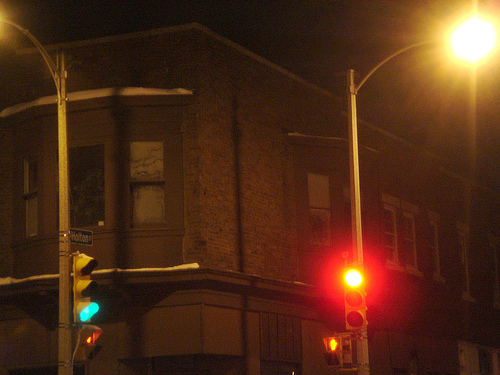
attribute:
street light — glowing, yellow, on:
[431, 5, 499, 76]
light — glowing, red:
[317, 250, 393, 309]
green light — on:
[76, 302, 100, 322]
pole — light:
[55, 106, 71, 374]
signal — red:
[342, 251, 370, 332]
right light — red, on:
[343, 268, 364, 287]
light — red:
[329, 338, 340, 354]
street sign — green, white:
[69, 227, 96, 246]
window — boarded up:
[128, 137, 169, 226]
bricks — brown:
[187, 105, 287, 257]